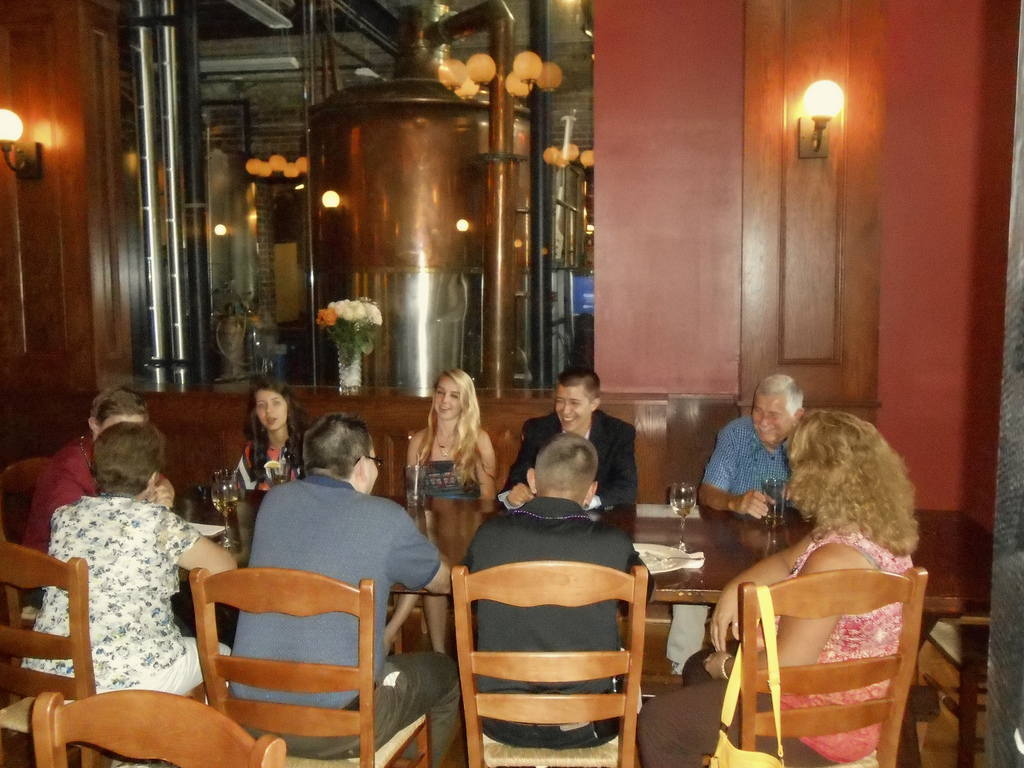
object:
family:
[637, 408, 921, 768]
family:
[666, 374, 804, 675]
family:
[496, 366, 639, 511]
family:
[458, 432, 657, 750]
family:
[228, 413, 459, 767]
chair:
[737, 566, 929, 768]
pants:
[240, 651, 462, 767]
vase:
[338, 345, 363, 393]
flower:
[343, 304, 368, 320]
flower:
[364, 303, 382, 325]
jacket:
[458, 496, 655, 696]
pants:
[636, 638, 838, 768]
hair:
[416, 368, 495, 492]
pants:
[96, 637, 232, 696]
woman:
[234, 377, 312, 491]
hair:
[242, 377, 309, 483]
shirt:
[20, 493, 203, 691]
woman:
[21, 421, 238, 706]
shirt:
[229, 474, 442, 710]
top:
[757, 522, 914, 763]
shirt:
[702, 415, 792, 495]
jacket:
[496, 409, 639, 510]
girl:
[383, 369, 496, 657]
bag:
[708, 584, 785, 768]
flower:
[316, 307, 338, 325]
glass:
[670, 482, 697, 552]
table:
[170, 486, 994, 768]